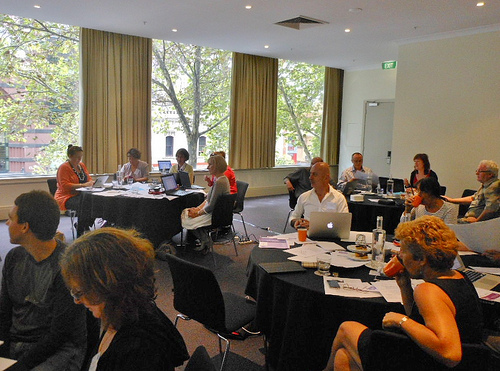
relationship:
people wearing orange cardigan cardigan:
[54, 144, 96, 235] [55, 158, 93, 212]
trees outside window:
[5, 45, 310, 162] [5, 47, 322, 157]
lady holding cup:
[324, 211, 496, 369] [378, 250, 410, 281]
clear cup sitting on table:
[319, 254, 331, 273] [259, 252, 386, 308]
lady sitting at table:
[324, 214, 485, 371] [352, 195, 405, 229]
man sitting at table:
[288, 162, 350, 231] [352, 195, 405, 229]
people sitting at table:
[181, 155, 231, 254] [130, 190, 171, 240]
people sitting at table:
[54, 144, 96, 235] [130, 190, 171, 240]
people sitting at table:
[51, 146, 94, 207] [75, 172, 200, 223]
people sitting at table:
[121, 142, 145, 176] [75, 172, 200, 223]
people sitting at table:
[172, 147, 192, 179] [75, 172, 200, 223]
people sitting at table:
[205, 157, 237, 222] [75, 172, 200, 223]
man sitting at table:
[288, 162, 350, 231] [75, 172, 200, 223]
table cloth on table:
[75, 186, 200, 225] [75, 172, 200, 223]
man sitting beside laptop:
[288, 160, 348, 230] [303, 212, 351, 239]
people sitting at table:
[181, 155, 231, 254] [76, 180, 201, 240]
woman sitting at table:
[202, 147, 238, 191] [76, 180, 201, 240]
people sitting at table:
[168, 148, 193, 185] [76, 180, 201, 240]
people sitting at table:
[119, 148, 150, 185] [76, 180, 201, 240]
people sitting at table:
[54, 144, 96, 235] [76, 180, 201, 240]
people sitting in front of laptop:
[181, 155, 231, 254] [158, 168, 194, 198]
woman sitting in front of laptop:
[202, 147, 238, 191] [177, 167, 207, 192]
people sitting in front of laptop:
[181, 155, 231, 254] [154, 158, 173, 176]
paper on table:
[269, 217, 366, 297] [238, 230, 497, 369]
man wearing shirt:
[288, 162, 350, 231] [284, 182, 348, 236]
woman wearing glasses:
[60, 226, 188, 369] [67, 281, 90, 302]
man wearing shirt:
[288, 162, 350, 231] [287, 184, 352, 237]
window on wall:
[273, 55, 324, 167] [396, 52, 487, 149]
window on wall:
[148, 36, 232, 170] [396, 52, 487, 149]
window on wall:
[0, 12, 83, 179] [396, 52, 487, 149]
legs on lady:
[312, 315, 452, 367] [324, 214, 485, 371]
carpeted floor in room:
[238, 188, 295, 243] [33, 37, 486, 342]